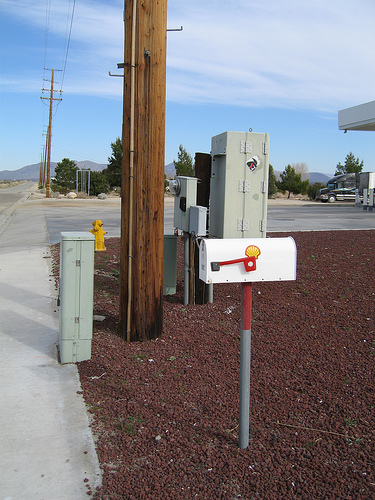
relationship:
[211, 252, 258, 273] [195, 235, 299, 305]
flag attached to mailbox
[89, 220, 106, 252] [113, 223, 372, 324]
fire hydrant for fire on gravel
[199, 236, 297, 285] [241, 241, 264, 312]
box with flag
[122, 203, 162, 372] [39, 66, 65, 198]
wooden electrical poles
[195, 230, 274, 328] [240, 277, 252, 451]
stake inserted into pole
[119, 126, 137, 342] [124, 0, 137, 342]
long tan weather proof lining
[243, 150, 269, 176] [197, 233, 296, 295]
sticker on side of box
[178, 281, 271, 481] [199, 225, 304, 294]
pole holding mail box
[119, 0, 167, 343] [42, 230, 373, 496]
pole in brown gravel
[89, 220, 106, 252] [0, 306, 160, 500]
fire hydrant for fire in gravel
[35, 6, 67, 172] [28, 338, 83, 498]
power lines on side of road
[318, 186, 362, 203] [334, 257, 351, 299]
car stopped to fill up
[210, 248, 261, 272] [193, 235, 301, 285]
red sign on mailbox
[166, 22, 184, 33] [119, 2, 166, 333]
hook pieces sticking out of pole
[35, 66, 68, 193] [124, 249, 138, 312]
poles are brown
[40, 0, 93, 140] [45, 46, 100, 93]
wires attached to poles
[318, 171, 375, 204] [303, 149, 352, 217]
car parked in a parking lot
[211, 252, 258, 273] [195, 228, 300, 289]
flag on a mailbox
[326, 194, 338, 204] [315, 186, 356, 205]
wheel of a car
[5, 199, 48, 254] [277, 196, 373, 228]
entrance to parking lot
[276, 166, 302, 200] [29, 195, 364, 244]
tree by a parking lot